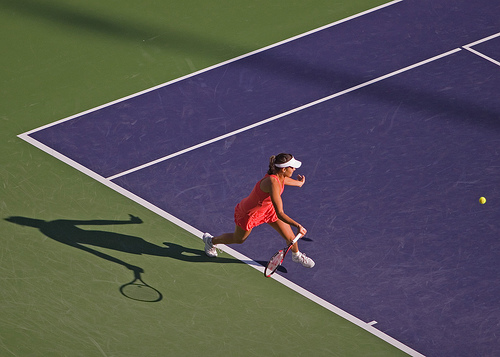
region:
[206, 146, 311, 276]
A woman playing tennis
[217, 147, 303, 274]
A woman in a tennis dress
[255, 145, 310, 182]
A white sun visor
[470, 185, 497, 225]
A yellow tennis ball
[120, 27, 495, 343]
A blue tennis court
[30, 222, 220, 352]
Green out of bounds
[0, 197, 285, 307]
A shadow of a woman tennis player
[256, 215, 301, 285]
A tennis racket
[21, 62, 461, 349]
White lines on the tennis court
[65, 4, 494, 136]
A shadow of a pole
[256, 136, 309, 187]
woman wearing a visor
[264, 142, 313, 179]
the visor is white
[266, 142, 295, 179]
woman's hair in pony tail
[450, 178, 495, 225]
the ball is in air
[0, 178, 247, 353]
shadow of woman on court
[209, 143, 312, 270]
woman wearing red dress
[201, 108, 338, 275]
woman is playing tennis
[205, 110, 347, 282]
woman holding a tennis racket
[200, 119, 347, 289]
woman's shoes are white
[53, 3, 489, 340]
tennis court is blue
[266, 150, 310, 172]
a white visor hat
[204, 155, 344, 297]
a female tennis player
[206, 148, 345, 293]
a tennis player about to hit a ball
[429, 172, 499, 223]
a yellow ball on a blue tennis court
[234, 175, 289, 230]
a woman wearing a red short dress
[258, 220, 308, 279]
a red and black tennis racket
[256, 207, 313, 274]
a woman holding a tennis racket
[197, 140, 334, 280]
woman running toward a ball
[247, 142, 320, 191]
woman wearing a white visor hat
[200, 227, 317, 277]
woman wearing white sneakers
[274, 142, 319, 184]
Woman wearing white visor.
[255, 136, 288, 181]
Woman has brown hair.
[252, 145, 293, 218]
Woman's hair is in a pony tail.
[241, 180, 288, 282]
Woman is wearing a pink dress.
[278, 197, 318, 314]
Woman is holding a tennis racket.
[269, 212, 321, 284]
White grip on tennis racket.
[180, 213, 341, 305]
Woman is wearing white shoes.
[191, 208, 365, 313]
Woman is wearing white socks.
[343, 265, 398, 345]
White lines on tennis court.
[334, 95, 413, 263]
Tennis court is blue.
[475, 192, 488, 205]
a small tennis ball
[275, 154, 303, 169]
a white visor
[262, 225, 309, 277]
a red and white racket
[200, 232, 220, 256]
a woman's white tennis shoe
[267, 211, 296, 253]
the leg of a woman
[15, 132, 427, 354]
a long white line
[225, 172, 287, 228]
a woman's sleeveless dress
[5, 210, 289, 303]
the shadow of the woman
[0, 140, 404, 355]
a green section of the court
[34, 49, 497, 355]
a purple section of the court